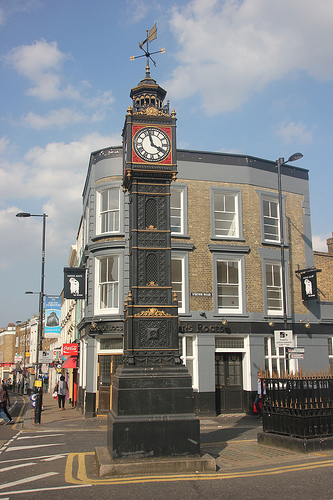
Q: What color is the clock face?
A: White.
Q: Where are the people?
A: On the sidewalk.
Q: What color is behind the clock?
A: Red.